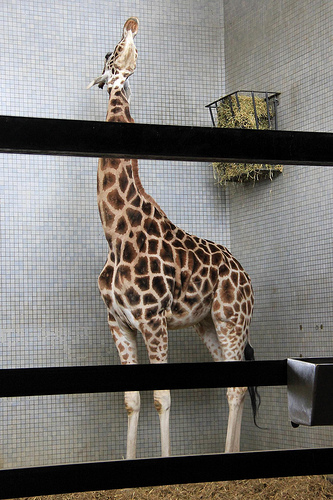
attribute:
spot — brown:
[142, 293, 156, 303]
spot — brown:
[210, 312, 226, 327]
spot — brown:
[163, 236, 205, 274]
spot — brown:
[137, 348, 173, 387]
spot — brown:
[118, 166, 127, 193]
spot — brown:
[146, 239, 157, 252]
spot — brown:
[122, 241, 137, 262]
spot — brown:
[160, 240, 173, 262]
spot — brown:
[143, 217, 161, 237]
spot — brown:
[186, 249, 201, 274]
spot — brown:
[220, 279, 235, 301]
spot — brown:
[112, 200, 146, 230]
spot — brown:
[224, 306, 233, 318]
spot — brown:
[134, 276, 150, 290]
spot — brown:
[217, 263, 229, 276]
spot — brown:
[144, 325, 154, 341]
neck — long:
[95, 81, 139, 152]